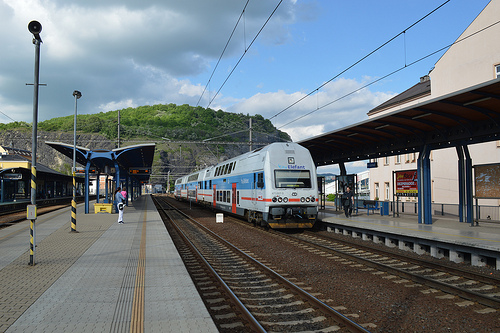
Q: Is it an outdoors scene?
A: Yes, it is outdoors.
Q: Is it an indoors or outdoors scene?
A: It is outdoors.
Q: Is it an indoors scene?
A: No, it is outdoors.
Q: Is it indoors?
A: No, it is outdoors.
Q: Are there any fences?
A: No, there are no fences.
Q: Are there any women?
A: Yes, there is a woman.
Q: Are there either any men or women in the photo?
A: Yes, there is a woman.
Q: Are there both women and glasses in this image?
A: No, there is a woman but no glasses.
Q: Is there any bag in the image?
A: No, there are no bags.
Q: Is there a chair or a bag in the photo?
A: No, there are no bags or chairs.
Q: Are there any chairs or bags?
A: No, there are no bags or chairs.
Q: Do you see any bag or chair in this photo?
A: No, there are no bags or chairs.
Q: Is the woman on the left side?
A: Yes, the woman is on the left of the image.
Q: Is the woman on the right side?
A: No, the woman is on the left of the image.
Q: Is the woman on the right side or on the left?
A: The woman is on the left of the image.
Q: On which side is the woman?
A: The woman is on the left of the image.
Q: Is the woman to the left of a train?
A: Yes, the woman is to the left of a train.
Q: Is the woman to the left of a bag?
A: No, the woman is to the left of a train.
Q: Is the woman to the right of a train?
A: No, the woman is to the left of a train.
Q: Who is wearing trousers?
A: The woman is wearing trousers.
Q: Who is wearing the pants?
A: The woman is wearing trousers.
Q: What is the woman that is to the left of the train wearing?
A: The woman is wearing trousers.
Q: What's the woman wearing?
A: The woman is wearing trousers.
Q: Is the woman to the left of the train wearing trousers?
A: Yes, the woman is wearing trousers.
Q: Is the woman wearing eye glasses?
A: No, the woman is wearing trousers.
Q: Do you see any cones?
A: No, there are no cones.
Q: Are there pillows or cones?
A: No, there are no cones or pillows.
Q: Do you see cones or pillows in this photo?
A: No, there are no cones or pillows.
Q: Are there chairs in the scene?
A: No, there are no chairs.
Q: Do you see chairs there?
A: No, there are no chairs.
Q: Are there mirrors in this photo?
A: No, there are no mirrors.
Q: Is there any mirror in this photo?
A: No, there are no mirrors.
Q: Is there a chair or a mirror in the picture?
A: No, there are no mirrors or chairs.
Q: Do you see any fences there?
A: No, there are no fences.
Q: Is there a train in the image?
A: Yes, there is a train.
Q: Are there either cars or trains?
A: Yes, there is a train.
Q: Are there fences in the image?
A: No, there are no fences.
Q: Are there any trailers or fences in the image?
A: No, there are no fences or trailers.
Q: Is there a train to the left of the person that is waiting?
A: No, the train is to the right of the person.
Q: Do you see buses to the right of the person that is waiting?
A: No, there is a train to the right of the person.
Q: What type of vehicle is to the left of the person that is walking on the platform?
A: The vehicle is a train.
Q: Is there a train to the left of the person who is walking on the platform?
A: Yes, there is a train to the left of the person.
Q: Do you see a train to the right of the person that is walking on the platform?
A: No, the train is to the left of the person.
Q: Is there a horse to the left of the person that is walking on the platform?
A: No, there is a train to the left of the person.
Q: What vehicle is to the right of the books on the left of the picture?
A: The vehicle is a train.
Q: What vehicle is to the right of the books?
A: The vehicle is a train.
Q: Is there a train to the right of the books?
A: Yes, there is a train to the right of the books.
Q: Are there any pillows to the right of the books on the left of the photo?
A: No, there is a train to the right of the books.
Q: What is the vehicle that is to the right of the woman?
A: The vehicle is a train.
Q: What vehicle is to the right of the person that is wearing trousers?
A: The vehicle is a train.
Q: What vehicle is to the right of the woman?
A: The vehicle is a train.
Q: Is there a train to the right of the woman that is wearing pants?
A: Yes, there is a train to the right of the woman.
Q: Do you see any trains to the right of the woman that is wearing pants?
A: Yes, there is a train to the right of the woman.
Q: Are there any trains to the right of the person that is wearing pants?
A: Yes, there is a train to the right of the woman.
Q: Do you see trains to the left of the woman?
A: No, the train is to the right of the woman.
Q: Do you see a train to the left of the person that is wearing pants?
A: No, the train is to the right of the woman.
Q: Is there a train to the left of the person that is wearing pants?
A: No, the train is to the right of the woman.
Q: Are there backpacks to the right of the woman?
A: No, there is a train to the right of the woman.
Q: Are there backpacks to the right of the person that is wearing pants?
A: No, there is a train to the right of the woman.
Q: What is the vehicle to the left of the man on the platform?
A: The vehicle is a train.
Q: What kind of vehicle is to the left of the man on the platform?
A: The vehicle is a train.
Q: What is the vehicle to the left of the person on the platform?
A: The vehicle is a train.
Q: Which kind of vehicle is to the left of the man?
A: The vehicle is a train.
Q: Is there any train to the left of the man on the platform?
A: Yes, there is a train to the left of the man.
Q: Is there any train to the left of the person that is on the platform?
A: Yes, there is a train to the left of the man.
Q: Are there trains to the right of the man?
A: No, the train is to the left of the man.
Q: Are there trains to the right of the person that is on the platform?
A: No, the train is to the left of the man.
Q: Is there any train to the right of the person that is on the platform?
A: No, the train is to the left of the man.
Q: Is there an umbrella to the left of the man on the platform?
A: No, there is a train to the left of the man.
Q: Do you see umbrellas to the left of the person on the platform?
A: No, there is a train to the left of the man.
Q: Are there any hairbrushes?
A: No, there are no hairbrushes.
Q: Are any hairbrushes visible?
A: No, there are no hairbrushes.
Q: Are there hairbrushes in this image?
A: No, there are no hairbrushes.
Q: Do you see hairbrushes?
A: No, there are no hairbrushes.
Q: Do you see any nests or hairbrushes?
A: No, there are no hairbrushes or nests.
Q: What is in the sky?
A: The clouds are in the sky.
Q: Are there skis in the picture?
A: No, there are no skis.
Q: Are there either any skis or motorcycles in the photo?
A: No, there are no skis or motorcycles.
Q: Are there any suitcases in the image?
A: No, there are no suitcases.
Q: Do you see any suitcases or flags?
A: No, there are no suitcases or flags.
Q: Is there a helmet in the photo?
A: No, there are no helmets.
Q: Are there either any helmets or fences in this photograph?
A: No, there are no helmets or fences.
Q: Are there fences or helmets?
A: No, there are no helmets or fences.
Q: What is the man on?
A: The man is on the platform.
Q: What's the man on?
A: The man is on the platform.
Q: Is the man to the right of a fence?
A: No, the man is to the right of a train.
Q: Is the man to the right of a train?
A: Yes, the man is to the right of a train.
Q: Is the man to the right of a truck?
A: No, the man is to the right of a train.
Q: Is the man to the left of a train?
A: No, the man is to the right of a train.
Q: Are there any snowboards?
A: No, there are no snowboards.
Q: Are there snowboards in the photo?
A: No, there are no snowboards.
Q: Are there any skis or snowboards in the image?
A: No, there are no snowboards or skis.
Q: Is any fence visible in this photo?
A: No, there are no fences.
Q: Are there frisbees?
A: No, there are no frisbees.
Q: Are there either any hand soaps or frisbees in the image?
A: No, there are no frisbees or hand soaps.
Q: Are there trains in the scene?
A: Yes, there is a train.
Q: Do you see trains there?
A: Yes, there is a train.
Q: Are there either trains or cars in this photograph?
A: Yes, there is a train.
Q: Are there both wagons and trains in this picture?
A: No, there is a train but no wagons.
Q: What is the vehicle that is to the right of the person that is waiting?
A: The vehicle is a train.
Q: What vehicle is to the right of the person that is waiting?
A: The vehicle is a train.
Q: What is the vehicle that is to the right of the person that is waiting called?
A: The vehicle is a train.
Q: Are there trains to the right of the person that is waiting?
A: Yes, there is a train to the right of the person.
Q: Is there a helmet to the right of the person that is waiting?
A: No, there is a train to the right of the person.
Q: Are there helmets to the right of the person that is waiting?
A: No, there is a train to the right of the person.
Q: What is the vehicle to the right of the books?
A: The vehicle is a train.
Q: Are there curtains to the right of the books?
A: No, there is a train to the right of the books.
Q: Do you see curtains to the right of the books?
A: No, there is a train to the right of the books.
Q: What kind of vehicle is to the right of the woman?
A: The vehicle is a train.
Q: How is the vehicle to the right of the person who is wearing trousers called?
A: The vehicle is a train.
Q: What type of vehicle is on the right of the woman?
A: The vehicle is a train.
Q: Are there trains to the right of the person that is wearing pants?
A: Yes, there is a train to the right of the woman.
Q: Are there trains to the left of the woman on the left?
A: No, the train is to the right of the woman.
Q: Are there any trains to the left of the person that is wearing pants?
A: No, the train is to the right of the woman.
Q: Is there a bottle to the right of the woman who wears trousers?
A: No, there is a train to the right of the woman.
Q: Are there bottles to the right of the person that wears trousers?
A: No, there is a train to the right of the woman.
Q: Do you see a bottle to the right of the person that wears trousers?
A: No, there is a train to the right of the woman.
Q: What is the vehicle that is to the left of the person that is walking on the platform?
A: The vehicle is a train.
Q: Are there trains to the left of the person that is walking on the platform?
A: Yes, there is a train to the left of the person.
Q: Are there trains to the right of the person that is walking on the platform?
A: No, the train is to the left of the person.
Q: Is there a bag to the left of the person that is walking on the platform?
A: No, there is a train to the left of the person.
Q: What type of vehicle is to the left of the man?
A: The vehicle is a train.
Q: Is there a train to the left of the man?
A: Yes, there is a train to the left of the man.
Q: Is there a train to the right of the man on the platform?
A: No, the train is to the left of the man.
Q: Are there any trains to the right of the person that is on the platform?
A: No, the train is to the left of the man.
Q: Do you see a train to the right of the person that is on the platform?
A: No, the train is to the left of the man.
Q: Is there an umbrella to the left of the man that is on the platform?
A: No, there is a train to the left of the man.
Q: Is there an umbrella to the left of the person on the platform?
A: No, there is a train to the left of the man.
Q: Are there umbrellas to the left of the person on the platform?
A: No, there is a train to the left of the man.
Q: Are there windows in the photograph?
A: Yes, there is a window.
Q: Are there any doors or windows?
A: Yes, there is a window.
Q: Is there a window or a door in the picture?
A: Yes, there is a window.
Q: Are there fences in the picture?
A: No, there are no fences.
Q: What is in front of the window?
A: The sign is in front of the window.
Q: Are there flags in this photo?
A: No, there are no flags.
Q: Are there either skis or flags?
A: No, there are no flags or skis.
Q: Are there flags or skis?
A: No, there are no flags or skis.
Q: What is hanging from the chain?
A: The sign is hanging from the chain.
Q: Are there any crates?
A: No, there are no crates.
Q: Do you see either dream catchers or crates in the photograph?
A: No, there are no crates or dream catchers.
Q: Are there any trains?
A: Yes, there is a train.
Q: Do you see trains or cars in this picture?
A: Yes, there is a train.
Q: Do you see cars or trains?
A: Yes, there is a train.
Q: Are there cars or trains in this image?
A: Yes, there is a train.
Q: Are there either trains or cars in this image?
A: Yes, there is a train.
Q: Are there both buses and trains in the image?
A: No, there is a train but no buses.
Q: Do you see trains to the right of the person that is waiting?
A: Yes, there is a train to the right of the person.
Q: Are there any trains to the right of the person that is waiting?
A: Yes, there is a train to the right of the person.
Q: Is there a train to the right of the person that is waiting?
A: Yes, there is a train to the right of the person.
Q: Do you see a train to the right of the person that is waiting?
A: Yes, there is a train to the right of the person.